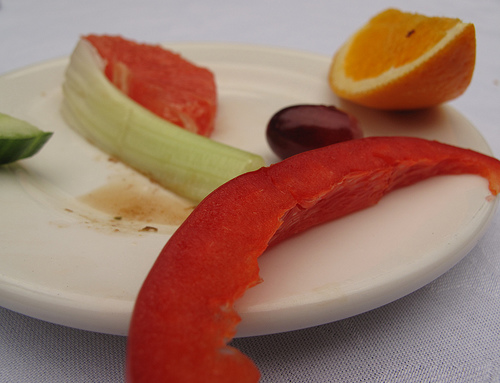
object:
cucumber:
[1, 103, 58, 168]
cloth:
[0, 0, 499, 382]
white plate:
[0, 36, 499, 340]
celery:
[58, 30, 267, 204]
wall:
[0, 2, 498, 157]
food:
[123, 134, 497, 383]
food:
[83, 33, 219, 133]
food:
[264, 100, 362, 158]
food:
[327, 3, 475, 114]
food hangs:
[123, 136, 499, 383]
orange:
[328, 7, 487, 112]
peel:
[294, 20, 479, 112]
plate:
[2, 27, 499, 364]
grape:
[265, 99, 326, 146]